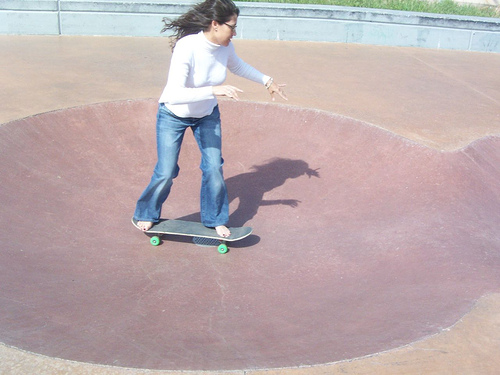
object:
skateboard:
[131, 217, 253, 254]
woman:
[133, 0, 288, 237]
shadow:
[144, 158, 321, 247]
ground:
[0, 34, 499, 375]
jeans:
[133, 104, 229, 229]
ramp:
[1, 97, 500, 373]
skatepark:
[1, 1, 499, 374]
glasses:
[223, 22, 236, 32]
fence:
[0, 0, 499, 53]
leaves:
[236, 0, 500, 19]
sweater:
[158, 30, 271, 118]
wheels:
[150, 235, 161, 246]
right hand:
[214, 86, 243, 101]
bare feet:
[136, 215, 232, 240]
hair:
[160, 0, 240, 45]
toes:
[221, 234, 230, 239]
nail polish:
[143, 227, 146, 232]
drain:
[193, 236, 223, 248]